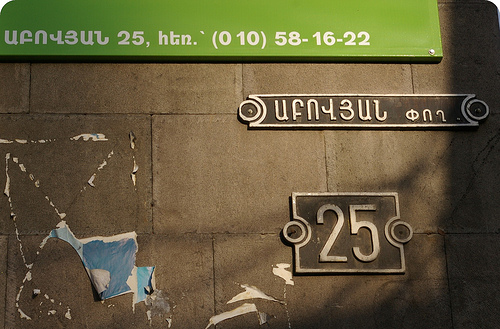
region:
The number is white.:
[116, 25, 132, 49]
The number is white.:
[129, 20, 148, 50]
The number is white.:
[216, 28, 235, 48]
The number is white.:
[230, 23, 247, 53]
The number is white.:
[268, 23, 290, 50]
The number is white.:
[286, 25, 303, 51]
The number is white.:
[309, 27, 324, 49]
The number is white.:
[320, 24, 337, 51]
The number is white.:
[341, 25, 359, 50]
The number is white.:
[355, 23, 375, 50]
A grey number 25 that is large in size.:
[315, 202, 382, 263]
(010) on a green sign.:
[211, 27, 267, 51]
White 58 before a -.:
[271, 30, 300, 46]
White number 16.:
[313, 29, 335, 46]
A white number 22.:
[342, 30, 369, 47]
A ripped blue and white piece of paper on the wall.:
[55, 221, 157, 307]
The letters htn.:
[156, 27, 192, 46]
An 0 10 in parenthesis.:
[218, 28, 260, 46]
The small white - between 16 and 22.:
[332, 36, 344, 43]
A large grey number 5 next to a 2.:
[347, 202, 379, 261]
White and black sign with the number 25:
[291, 193, 406, 274]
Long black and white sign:
[247, 93, 479, 131]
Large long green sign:
[2, 2, 445, 60]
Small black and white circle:
[282, 218, 304, 243]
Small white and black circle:
[389, 218, 414, 242]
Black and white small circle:
[236, 101, 260, 121]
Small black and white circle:
[467, 99, 488, 118]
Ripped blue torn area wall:
[42, 219, 159, 301]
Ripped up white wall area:
[204, 261, 294, 325]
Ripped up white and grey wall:
[2, 128, 144, 318]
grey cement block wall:
[105, 93, 236, 285]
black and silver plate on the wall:
[271, 168, 433, 296]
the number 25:
[310, 199, 381, 262]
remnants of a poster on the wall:
[44, 200, 165, 327]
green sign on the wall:
[22, 12, 448, 71]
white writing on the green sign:
[7, 20, 381, 48]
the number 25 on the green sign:
[111, 23, 145, 49]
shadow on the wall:
[417, 156, 488, 300]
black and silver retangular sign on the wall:
[226, 77, 496, 140]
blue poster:
[97, 245, 131, 280]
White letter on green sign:
[3, 20, 23, 46]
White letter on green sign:
[17, 25, 35, 49]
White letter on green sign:
[30, 25, 49, 52]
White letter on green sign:
[47, 26, 64, 46]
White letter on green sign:
[64, 21, 77, 51]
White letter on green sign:
[75, 24, 98, 50]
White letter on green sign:
[88, 26, 118, 47]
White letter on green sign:
[152, 22, 199, 51]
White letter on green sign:
[203, 22, 383, 48]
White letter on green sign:
[2, 25, 198, 54]